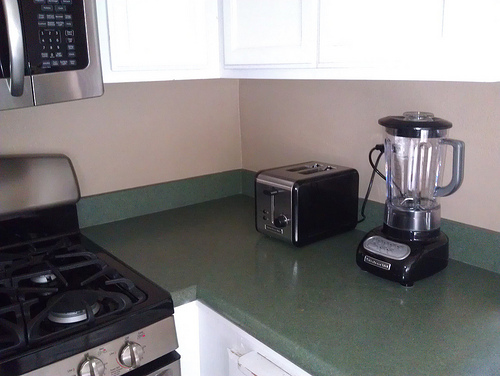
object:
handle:
[436, 136, 463, 195]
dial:
[118, 344, 145, 368]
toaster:
[250, 160, 361, 250]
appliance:
[252, 159, 359, 247]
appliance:
[354, 110, 464, 286]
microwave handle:
[3, 2, 25, 98]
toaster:
[235, 151, 372, 251]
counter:
[76, 188, 498, 375]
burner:
[0, 152, 180, 376]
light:
[143, 335, 145, 338]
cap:
[377, 112, 453, 130]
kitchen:
[0, 27, 499, 376]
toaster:
[220, 99, 383, 251]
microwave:
[0, 0, 102, 109]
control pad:
[28, 2, 87, 70]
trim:
[132, 334, 174, 373]